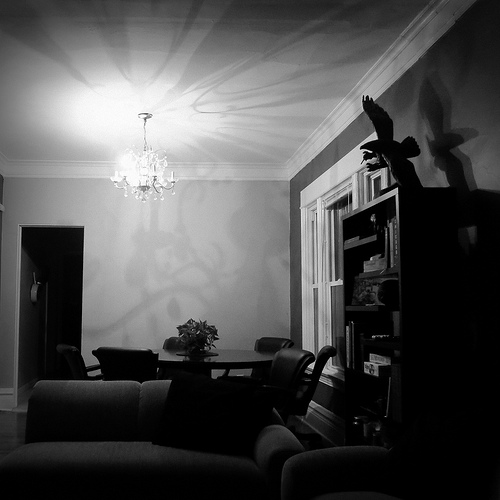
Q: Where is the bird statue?
A: On top of the shelf.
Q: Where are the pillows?
A: On the sofa.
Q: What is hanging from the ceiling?
A: A chandelier.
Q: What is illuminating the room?
A: The chandelier.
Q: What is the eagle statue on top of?
A: A book shelf.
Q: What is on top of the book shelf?
A: A statue of an eagle.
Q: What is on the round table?
A: A plant.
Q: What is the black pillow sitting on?
A: The couch.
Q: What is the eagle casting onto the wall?
A: A shadow.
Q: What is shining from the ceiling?
A: Light.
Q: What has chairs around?
A: Table.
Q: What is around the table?
A: Chairs.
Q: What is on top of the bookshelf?
A: Bird statue.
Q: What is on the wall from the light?
A: Shadows.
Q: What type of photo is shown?
A: Black and white.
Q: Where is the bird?
A: On the shelf.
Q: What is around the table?
A: Chairs.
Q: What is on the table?
A: A plant.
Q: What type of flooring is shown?
A: Hardwood.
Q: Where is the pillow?
A: On the couch.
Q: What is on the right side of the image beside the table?
A: Window.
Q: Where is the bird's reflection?
A: On the wall.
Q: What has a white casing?
A: The window.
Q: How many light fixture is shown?
A: 1.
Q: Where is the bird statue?
A: On the bookshelf.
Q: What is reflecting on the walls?
A: The chandelier light.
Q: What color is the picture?
A: Black and white.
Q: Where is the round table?
A: In the dining area.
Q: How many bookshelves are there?
A: One.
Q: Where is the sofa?
A: Closest to the camera.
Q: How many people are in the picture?
A: None.